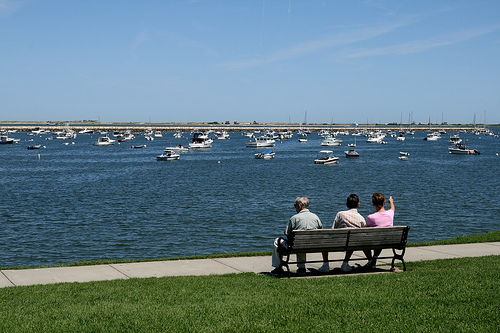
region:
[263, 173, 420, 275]
people in front the sea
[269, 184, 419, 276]
three people sit on a bench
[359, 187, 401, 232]
woman wears pink top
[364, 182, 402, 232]
woman is pointing with right hand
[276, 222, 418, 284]
bench is made of wood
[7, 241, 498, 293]
sidewalk in front a bench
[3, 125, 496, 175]
boats in the ocean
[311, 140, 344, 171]
white boat with roof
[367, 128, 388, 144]
the boat is white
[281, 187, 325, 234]
man has gray hair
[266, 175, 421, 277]
three people sitting on the bench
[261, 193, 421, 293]
wood and iron bench near grass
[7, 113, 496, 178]
water is very crowded with boats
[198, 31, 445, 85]
thin white clouds in the blue sky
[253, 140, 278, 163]
small boat with blue roof on it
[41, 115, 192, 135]
side of the ocean's shore line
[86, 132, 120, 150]
white boat floating on the water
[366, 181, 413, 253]
person pointing while wearing pink shirt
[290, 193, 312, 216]
man with gray hair and sunglasses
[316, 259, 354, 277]
person in middle wearing white shoes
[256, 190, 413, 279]
three people on a bench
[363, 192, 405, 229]
woman in a light pink shirt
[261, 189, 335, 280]
old man on a bench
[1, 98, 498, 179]
boats in the harbor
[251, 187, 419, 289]
people on a wooden bench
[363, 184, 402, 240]
woman pointing at boats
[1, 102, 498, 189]
recreational boats in the water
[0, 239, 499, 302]
cement sidewalk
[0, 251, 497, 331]
patch of green grass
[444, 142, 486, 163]
small motor boat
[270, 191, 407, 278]
three people sitting on a wooden bench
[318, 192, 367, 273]
a man sitting between a woman and another man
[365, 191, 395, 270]
a woman sitting on a bench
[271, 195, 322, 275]
a older man with gray hair sitting on a bench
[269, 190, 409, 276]
people sitting on a bench overlooking a river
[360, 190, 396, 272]
a woman pointing at boats on the river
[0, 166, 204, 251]
blue water in the river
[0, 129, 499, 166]
boats on the river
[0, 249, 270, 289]
a cement sidewalk beside the river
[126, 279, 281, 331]
green grass covering the ground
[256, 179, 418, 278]
bench by water with three people seated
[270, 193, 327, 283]
older gentleman in blue shirt and blue pants on bench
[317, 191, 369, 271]
younger gentelman wearing plaid shirt sitting on bench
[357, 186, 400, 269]
woman wearing pink shirt sitting on bench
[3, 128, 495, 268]
bright blue water of marina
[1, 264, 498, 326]
gren grass lining boardwalk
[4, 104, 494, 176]
many sail boats in black and white floating marina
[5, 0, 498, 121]
bright blue cloudless sky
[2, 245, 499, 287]
grey concrete sidewalk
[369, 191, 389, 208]
short dark hair on woman